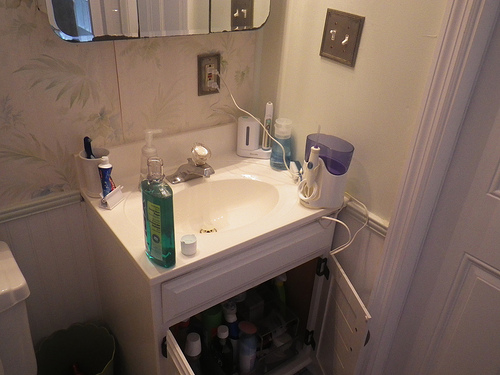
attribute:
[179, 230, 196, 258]
cap — white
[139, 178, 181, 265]
mouthwash — blue, green, open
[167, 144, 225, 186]
faucet — metal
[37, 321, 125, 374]
garbage pail — green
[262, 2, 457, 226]
wall — white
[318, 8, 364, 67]
light switch — up, down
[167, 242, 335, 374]
cabinet — full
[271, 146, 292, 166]
liquid — blue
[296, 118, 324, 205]
toothbrush — electric